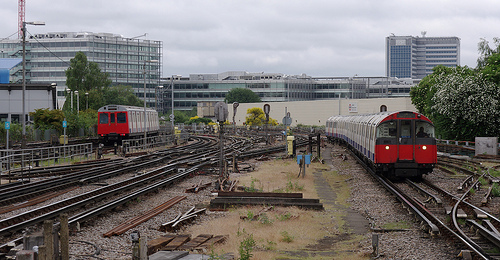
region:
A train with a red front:
[90, 99, 172, 142]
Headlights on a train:
[380, 140, 434, 152]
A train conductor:
[414, 121, 431, 138]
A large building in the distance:
[382, 28, 464, 85]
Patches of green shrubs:
[205, 170, 316, 257]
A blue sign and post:
[2, 116, 19, 171]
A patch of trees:
[404, 36, 499, 153]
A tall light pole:
[15, 16, 53, 141]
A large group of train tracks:
[4, 101, 319, 258]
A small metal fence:
[0, 142, 108, 166]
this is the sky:
[176, 0, 354, 69]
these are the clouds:
[193, 17, 242, 40]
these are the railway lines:
[421, 182, 488, 244]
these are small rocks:
[363, 186, 387, 208]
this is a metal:
[392, 188, 424, 230]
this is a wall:
[300, 98, 323, 120]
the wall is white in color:
[298, 105, 318, 110]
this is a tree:
[68, 59, 106, 101]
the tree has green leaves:
[236, 87, 248, 96]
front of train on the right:
[373, 120, 438, 167]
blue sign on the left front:
[5, 115, 14, 151]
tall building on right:
[387, 17, 464, 65]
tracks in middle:
[37, 170, 186, 210]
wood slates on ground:
[154, 218, 226, 250]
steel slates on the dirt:
[210, 184, 336, 206]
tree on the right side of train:
[437, 71, 496, 133]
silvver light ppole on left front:
[22, 12, 47, 119]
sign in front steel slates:
[214, 87, 231, 201]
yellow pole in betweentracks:
[285, 127, 295, 157]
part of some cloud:
[263, 12, 311, 52]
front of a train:
[374, 123, 428, 175]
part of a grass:
[256, 192, 288, 231]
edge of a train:
[116, 189, 136, 205]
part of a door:
[399, 143, 416, 171]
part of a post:
[213, 132, 227, 175]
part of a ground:
[287, 212, 317, 248]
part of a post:
[364, 223, 383, 252]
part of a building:
[255, 62, 294, 100]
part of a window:
[105, 115, 118, 122]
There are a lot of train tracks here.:
[43, 147, 295, 239]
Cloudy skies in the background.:
[166, 8, 369, 65]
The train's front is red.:
[326, 100, 447, 183]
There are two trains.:
[72, 72, 449, 194]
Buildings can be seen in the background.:
[10, 12, 451, 120]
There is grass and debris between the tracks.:
[161, 141, 377, 255]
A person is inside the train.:
[384, 110, 439, 165]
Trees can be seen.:
[33, 53, 117, 133]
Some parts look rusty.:
[136, 179, 331, 258]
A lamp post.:
[8, 9, 54, 142]